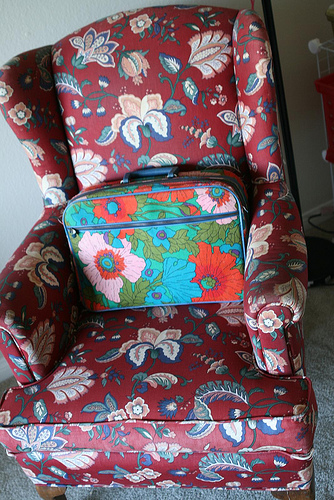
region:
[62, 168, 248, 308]
a small floral briefcase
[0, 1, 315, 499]
a floral upholstered living room chair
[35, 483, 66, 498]
a wooden chair leg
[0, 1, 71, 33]
a grey plastered wall behind the chair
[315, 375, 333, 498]
a grey shag carpet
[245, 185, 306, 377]
thick padded arm rest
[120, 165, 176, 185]
a blue briefcase handle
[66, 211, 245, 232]
a zipper on the briefcase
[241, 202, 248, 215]
the metal zipper pull grip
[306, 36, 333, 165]
a wire kitchen utility basket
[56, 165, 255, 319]
the case has flowers on it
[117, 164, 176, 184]
the case has a handle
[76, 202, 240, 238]
the case has a zipper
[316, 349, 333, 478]
the rug is gray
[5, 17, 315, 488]
a chair with a case on it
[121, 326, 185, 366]
the chair has a flower on it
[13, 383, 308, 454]
the chair is red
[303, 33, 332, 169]
the rack is white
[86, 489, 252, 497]
the carpet is under the chair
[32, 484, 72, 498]
the chair has a left leg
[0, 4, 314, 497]
small suitcase on chair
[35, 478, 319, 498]
two brown leg chairs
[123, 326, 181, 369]
flower design on chair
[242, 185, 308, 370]
arm rest on chair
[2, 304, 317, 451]
cushion on top of chair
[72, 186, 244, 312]
flower print on suitcase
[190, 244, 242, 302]
orange flower on suitcase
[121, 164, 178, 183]
blue handle on suitcase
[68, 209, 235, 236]
zipper on front of suitcase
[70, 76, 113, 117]
blue and white flowers on green stem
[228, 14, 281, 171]
Section of a sofa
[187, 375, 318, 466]
Section of a sofa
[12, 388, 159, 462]
Section of a sofa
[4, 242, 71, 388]
Section of a sofa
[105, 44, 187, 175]
Section of a sofa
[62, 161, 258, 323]
Section of a sofa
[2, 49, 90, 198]
Section of a sofa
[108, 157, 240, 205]
Section of a sofa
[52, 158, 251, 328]
This is a bag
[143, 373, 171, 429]
part of a chair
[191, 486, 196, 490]
part of a carpet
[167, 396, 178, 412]
edge of a seat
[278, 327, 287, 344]
part of a chair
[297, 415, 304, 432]
edge of a seat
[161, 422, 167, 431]
part of a field